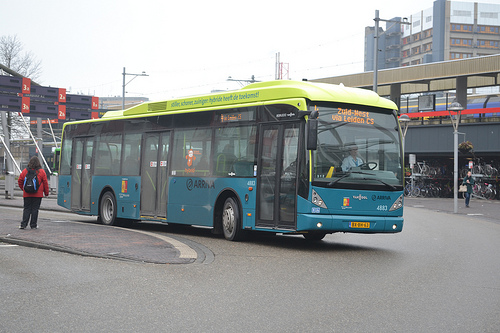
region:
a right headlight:
[305, 196, 333, 224]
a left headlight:
[385, 199, 407, 217]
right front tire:
[211, 182, 244, 238]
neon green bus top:
[68, 80, 395, 125]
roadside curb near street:
[0, 207, 202, 268]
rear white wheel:
[92, 182, 120, 234]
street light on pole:
[114, 63, 156, 102]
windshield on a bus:
[308, 120, 399, 195]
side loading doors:
[140, 123, 167, 216]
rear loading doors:
[69, 127, 97, 207]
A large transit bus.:
[53, 81, 432, 256]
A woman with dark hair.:
[14, 148, 51, 234]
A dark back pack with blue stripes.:
[18, 152, 49, 205]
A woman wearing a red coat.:
[11, 152, 51, 204]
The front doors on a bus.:
[251, 111, 301, 236]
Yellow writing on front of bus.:
[326, 101, 383, 128]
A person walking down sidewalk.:
[459, 152, 483, 217]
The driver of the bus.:
[338, 126, 393, 188]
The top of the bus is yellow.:
[108, 80, 400, 114]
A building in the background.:
[366, 6, 490, 60]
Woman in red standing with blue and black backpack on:
[9, 153, 54, 236]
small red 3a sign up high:
[20, 72, 32, 98]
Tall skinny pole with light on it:
[442, 89, 464, 221]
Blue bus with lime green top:
[38, 75, 418, 244]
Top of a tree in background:
[0, 35, 41, 81]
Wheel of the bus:
[212, 190, 244, 247]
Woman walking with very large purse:
[456, 165, 480, 217]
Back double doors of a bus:
[63, 126, 98, 221]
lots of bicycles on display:
[404, 153, 451, 200]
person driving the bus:
[336, 136, 378, 190]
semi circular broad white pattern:
[128, 226, 211, 264]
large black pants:
[18, 194, 50, 231]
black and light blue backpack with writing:
[20, 171, 45, 200]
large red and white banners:
[19, 75, 34, 115]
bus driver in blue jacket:
[341, 137, 383, 179]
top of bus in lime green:
[117, 82, 399, 112]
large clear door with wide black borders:
[253, 120, 308, 226]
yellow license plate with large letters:
[348, 216, 377, 243]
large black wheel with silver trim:
[211, 189, 247, 250]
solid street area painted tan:
[80, 269, 491, 326]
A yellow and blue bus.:
[58, 79, 419, 239]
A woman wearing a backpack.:
[10, 164, 51, 206]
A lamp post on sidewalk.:
[445, 94, 471, 216]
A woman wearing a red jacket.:
[14, 163, 54, 198]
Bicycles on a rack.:
[406, 161, 449, 197]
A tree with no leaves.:
[1, 37, 38, 77]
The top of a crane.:
[223, 72, 272, 90]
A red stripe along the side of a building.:
[403, 99, 498, 131]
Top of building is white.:
[401, 0, 499, 32]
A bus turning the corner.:
[55, 76, 420, 241]